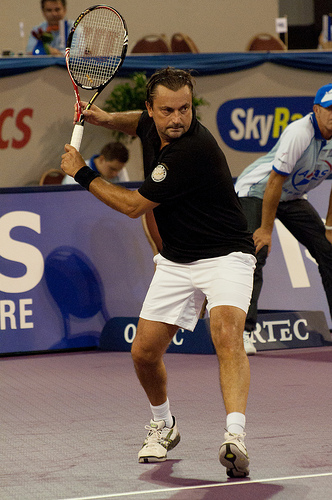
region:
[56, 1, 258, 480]
A TENNIS PLAYER HOLDING A TENNIS RACKET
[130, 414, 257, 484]
A PAIR OF TENNIS SHOES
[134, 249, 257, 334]
A PAIR OF WHITE SHORTS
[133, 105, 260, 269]
A BLACK TENNIS SHIRT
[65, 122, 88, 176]
THE WHITE HANDLE OF A TENNIS RACKET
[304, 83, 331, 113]
A BLUE AND WHITE HAT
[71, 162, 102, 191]
A BLACK WRIST BAND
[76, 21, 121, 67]
A W ON A TENNIS RACKET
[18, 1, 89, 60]
A MAN SITTING IN THE BACKGROUND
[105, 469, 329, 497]
A WHITE LINE ON THE TENNIS COURT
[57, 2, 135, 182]
Tennis racket being swung.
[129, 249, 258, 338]
White shorts on a man.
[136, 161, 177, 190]
Logo on black shirt.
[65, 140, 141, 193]
Man looking down in background.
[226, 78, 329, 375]
Man in white and blue hat bending forward.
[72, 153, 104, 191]
Black wrist warmer.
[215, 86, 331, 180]
Advertisement on back wall.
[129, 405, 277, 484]
Tennis shoes.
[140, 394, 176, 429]
White sock.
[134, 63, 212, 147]
Man with slicked back hair.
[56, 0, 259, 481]
man holding tennis racket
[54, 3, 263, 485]
man getting ready to swing tennis racket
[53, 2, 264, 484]
man wearing black wristband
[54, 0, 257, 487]
man wearing black collared shirt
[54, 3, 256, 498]
man wearing white shorts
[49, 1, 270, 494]
man wearing headband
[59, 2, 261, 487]
man wearing long white socks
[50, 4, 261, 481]
man wearing black and white tennis shoes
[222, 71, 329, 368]
man with hands on knees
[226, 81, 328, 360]
man wearing blue hat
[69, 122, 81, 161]
Handle of tennis racket is white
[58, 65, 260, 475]
Man holding tennis racket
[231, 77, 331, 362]
Man is bending over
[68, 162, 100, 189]
Wristband on wrist is black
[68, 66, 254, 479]
Man wearing black polo shirt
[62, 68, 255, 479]
Man wearing white shorts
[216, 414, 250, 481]
Foot is lifted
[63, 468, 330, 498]
White line on court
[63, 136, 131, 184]
Man is seated looking down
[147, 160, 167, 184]
Circle patch on black polo shirt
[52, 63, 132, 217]
man holding tennis racket with two hands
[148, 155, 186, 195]
patch on player's sleeve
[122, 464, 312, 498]
white line on the court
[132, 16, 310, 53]
empty chairs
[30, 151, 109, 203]
player has on wristband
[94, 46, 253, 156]
plant hanging behind the player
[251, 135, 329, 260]
man's hands on his knees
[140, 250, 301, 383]
player wearing white shorts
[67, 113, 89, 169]
tennis handle is white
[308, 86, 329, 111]
man is wearing blue ballcap